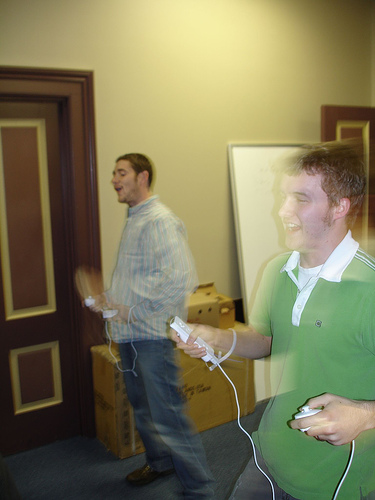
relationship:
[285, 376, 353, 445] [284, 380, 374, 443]
controller in hand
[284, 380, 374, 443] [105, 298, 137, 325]
hand in hand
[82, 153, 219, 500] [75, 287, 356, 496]
man playing wii game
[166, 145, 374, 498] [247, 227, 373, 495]
man in polo shirt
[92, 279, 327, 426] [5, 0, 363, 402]
boxes sitting next to wall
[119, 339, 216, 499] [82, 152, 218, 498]
jeans worn by man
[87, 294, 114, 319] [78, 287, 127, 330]
controller in hand